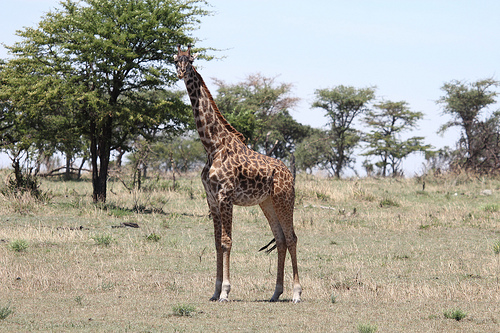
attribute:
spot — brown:
[218, 152, 230, 163]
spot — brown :
[188, 74, 200, 91]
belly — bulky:
[236, 172, 271, 209]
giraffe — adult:
[161, 47, 288, 260]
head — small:
[175, 44, 191, 77]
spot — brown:
[190, 96, 197, 107]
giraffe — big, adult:
[171, 44, 303, 301]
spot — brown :
[208, 175, 217, 182]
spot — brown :
[209, 123, 219, 135]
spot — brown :
[247, 162, 259, 177]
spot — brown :
[269, 165, 277, 175]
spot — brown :
[190, 89, 200, 98]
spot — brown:
[199, 124, 220, 145]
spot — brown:
[205, 109, 214, 130]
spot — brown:
[262, 165, 282, 183]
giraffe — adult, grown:
[154, 41, 310, 309]